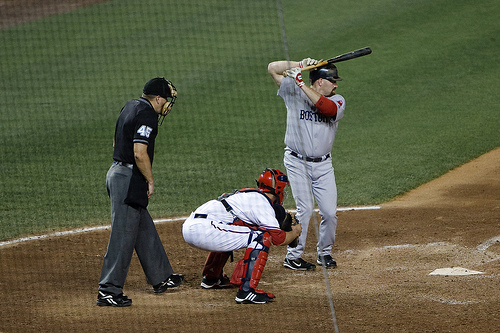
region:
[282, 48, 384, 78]
The bat in the batter's hand.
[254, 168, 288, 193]
The red helmet the catcher is wearing.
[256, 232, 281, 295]
The knee shield guard the catcher is wearing.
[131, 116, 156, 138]
The 45 on the sleeve of the umpire's shirt.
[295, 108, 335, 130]
The word Boston on the batter's shirt.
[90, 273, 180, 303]
The black and white sneakers the umpire is wearing.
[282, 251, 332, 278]
The black and white sneakers the batter is wearing.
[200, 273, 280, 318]
The black and white sneakers the catcher is wearing.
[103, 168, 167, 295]
The gray pants the umpire is wearing.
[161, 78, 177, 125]
The face guard shield the umpire is wearing.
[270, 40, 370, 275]
hitter in the batter's box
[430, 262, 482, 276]
white home plate with some dirt on it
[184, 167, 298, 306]
baseball catcher in a crouched position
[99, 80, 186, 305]
umpire in black behind the catcher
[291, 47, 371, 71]
black painted wooden baseball bat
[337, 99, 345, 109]
Boston Red Sox logo on the batter's left shoulder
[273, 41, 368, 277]
Kevin Youkilis with a bat, ready to hit the ball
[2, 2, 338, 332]
net screen to protect the fans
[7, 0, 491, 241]
green grass in foul territory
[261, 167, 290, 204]
red catcher's mask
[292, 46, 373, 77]
Baseball bat held by baseball player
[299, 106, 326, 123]
Team logo on baseball uniform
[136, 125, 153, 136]
Number on umpire uniform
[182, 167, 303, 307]
Catcher on a baseball team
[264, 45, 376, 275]
Batter preparing to swing at a pitch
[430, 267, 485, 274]
Home plate on a baseball diamond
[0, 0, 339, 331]
Catch net at a baseball park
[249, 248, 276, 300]
Shin guard worn by baseball catcher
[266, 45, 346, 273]
Man wearing a baseball uniform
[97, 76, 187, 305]
Umpired judging pitches at a baseball game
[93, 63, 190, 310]
This is a person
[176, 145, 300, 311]
This is a person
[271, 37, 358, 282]
This is a person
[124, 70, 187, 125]
Head of a person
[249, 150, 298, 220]
Head of a person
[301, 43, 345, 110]
Head of a person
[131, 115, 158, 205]
Hand of a person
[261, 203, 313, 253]
Hand of a person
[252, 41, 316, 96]
Hand of a person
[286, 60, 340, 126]
Hand of a person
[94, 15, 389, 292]
3 men playing baseball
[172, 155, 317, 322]
the catcher is squatting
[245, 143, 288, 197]
catcher wearing a helmet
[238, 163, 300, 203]
the helmet is red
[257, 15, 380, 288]
the player is standing on dirt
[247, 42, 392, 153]
the player is holding a bat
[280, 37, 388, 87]
the bat is black and tan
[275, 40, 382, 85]
the bat is made of wood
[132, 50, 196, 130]
the umpire is wearing a mask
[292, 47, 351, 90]
batter is wearing a helmet